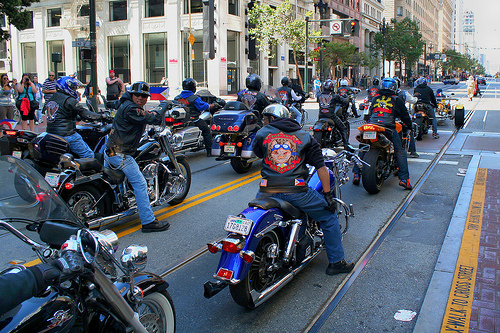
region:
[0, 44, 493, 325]
Group of motorcycles going down the road.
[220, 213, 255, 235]
License plate on a motorcycle.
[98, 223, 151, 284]
Lights of a motorcycle.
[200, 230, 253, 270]
Tail lights of a motorcycle.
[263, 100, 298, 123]
Helmet on a motorcycle rider.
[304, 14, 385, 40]
Red light in the air.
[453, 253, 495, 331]
Brick sidewalk beside road.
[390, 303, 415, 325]
Trash on the ground.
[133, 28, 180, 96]
Windows of a building.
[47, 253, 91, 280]
Glove on a hand.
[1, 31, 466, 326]
several men on motorcycles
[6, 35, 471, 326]
several motorcycles on the street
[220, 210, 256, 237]
the license plate on a motorcycle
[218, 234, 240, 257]
the brake light on a motorcycle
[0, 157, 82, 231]
the windshield of a motorcycle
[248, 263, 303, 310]
the muffler of a motorcycle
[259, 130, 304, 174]
the emblem on the back of a leather jacket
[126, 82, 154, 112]
a man looking back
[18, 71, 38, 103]
a woman taking a picture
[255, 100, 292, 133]
a man wearing a silver helmet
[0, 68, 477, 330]
several people riding motorbikes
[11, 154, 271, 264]
two parallel yellow lines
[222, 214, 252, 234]
license plate on the back of the bike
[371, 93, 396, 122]
design on the back of the jacket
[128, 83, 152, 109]
head is turned to the side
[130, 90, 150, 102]
sunglasses on the face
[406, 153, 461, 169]
white line painted on the ground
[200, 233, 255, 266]
red lights on the back of the bike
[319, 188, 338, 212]
hand is resting on the leg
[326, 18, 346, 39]
red, white, and black sign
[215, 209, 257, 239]
License plate on back of motorcycle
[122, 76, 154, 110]
Man wearing motorcycle helmet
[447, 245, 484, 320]
Yellow safety line on a sidewalk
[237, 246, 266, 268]
Right tail light of a motorcycle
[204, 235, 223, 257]
Left tail light of a motorcycle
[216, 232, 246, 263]
Right brake light of a motorcycle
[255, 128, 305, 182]
Logo on the back of motorcycle jacket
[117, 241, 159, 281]
Headlight light of a motorcycle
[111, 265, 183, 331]
Front wheel of a motorcycle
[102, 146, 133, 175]
Chain attached to a wallet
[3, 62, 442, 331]
group of motorcycle riders at a stop.